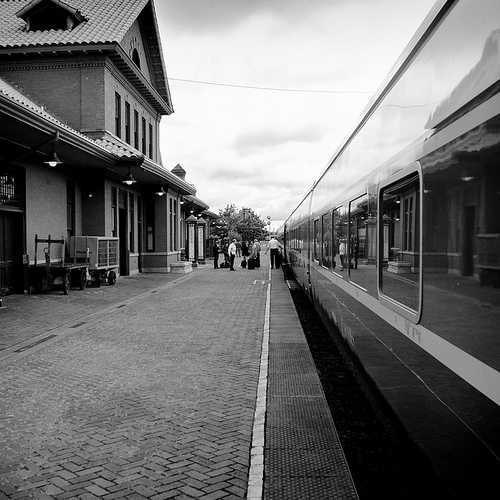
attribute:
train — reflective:
[233, 89, 445, 293]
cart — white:
[68, 235, 120, 284]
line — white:
[243, 247, 273, 498]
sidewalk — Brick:
[0, 235, 366, 499]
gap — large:
[281, 265, 449, 499]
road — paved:
[0, 255, 363, 498]